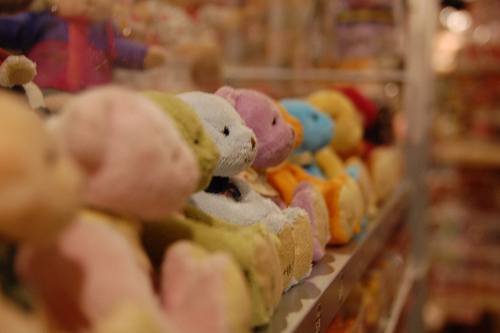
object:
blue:
[280, 98, 335, 177]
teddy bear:
[0, 84, 400, 333]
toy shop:
[0, 0, 500, 333]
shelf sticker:
[338, 276, 347, 301]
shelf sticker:
[313, 303, 321, 333]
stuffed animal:
[45, 86, 229, 333]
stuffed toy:
[215, 86, 324, 261]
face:
[240, 98, 296, 171]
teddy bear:
[0, 89, 300, 333]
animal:
[0, 88, 391, 333]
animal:
[0, 0, 169, 92]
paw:
[142, 42, 167, 71]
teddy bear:
[0, 0, 162, 93]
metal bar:
[403, 0, 437, 333]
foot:
[266, 211, 313, 290]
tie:
[207, 176, 242, 201]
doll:
[0, 0, 162, 92]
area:
[418, 14, 493, 320]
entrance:
[408, 0, 499, 333]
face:
[294, 100, 335, 147]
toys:
[0, 87, 397, 333]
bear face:
[184, 94, 258, 175]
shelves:
[0, 0, 498, 331]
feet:
[370, 146, 405, 201]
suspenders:
[66, 16, 88, 93]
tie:
[67, 15, 86, 93]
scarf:
[204, 176, 241, 199]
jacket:
[240, 168, 280, 196]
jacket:
[139, 216, 192, 271]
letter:
[283, 262, 294, 276]